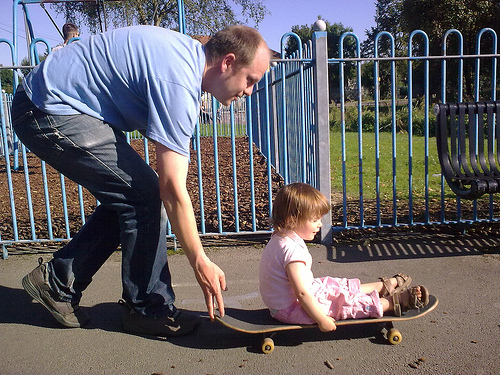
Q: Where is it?
A: This is at the walkway.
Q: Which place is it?
A: It is a walkway.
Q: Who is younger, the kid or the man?
A: The kid is younger than the man.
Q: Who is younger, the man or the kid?
A: The kid is younger than the man.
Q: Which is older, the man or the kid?
A: The man is older than the kid.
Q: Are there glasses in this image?
A: No, there are no glasses.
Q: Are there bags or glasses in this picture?
A: No, there are no glasses or bags.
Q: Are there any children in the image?
A: Yes, there is a child.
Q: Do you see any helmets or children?
A: Yes, there is a child.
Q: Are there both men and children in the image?
A: Yes, there are both a child and a man.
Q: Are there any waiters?
A: No, there are no waiters.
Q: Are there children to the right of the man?
A: Yes, there is a child to the right of the man.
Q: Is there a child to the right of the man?
A: Yes, there is a child to the right of the man.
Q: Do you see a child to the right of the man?
A: Yes, there is a child to the right of the man.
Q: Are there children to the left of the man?
A: No, the child is to the right of the man.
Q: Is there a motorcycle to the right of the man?
A: No, there is a child to the right of the man.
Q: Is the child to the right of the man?
A: Yes, the child is to the right of the man.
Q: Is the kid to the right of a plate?
A: No, the kid is to the right of the man.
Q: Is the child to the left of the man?
A: No, the child is to the right of the man.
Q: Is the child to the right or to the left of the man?
A: The child is to the right of the man.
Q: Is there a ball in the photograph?
A: No, there are no balls.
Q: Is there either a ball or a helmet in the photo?
A: No, there are no balls or helmets.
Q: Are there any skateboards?
A: Yes, there is a skateboard.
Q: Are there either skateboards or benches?
A: Yes, there is a skateboard.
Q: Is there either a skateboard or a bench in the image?
A: Yes, there is a skateboard.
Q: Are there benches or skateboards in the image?
A: Yes, there is a skateboard.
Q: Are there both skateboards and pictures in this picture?
A: No, there is a skateboard but no pictures.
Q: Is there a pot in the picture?
A: No, there are no pots.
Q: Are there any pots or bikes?
A: No, there are no pots or bikes.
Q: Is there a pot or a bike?
A: No, there are no pots or bikes.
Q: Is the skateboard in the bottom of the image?
A: Yes, the skateboard is in the bottom of the image.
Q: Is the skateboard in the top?
A: No, the skateboard is in the bottom of the image.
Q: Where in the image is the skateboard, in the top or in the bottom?
A: The skateboard is in the bottom of the image.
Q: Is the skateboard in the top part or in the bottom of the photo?
A: The skateboard is in the bottom of the image.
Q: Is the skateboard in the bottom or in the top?
A: The skateboard is in the bottom of the image.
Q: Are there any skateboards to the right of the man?
A: Yes, there is a skateboard to the right of the man.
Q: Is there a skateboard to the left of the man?
A: No, the skateboard is to the right of the man.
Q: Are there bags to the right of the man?
A: No, there is a skateboard to the right of the man.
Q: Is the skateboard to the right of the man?
A: Yes, the skateboard is to the right of the man.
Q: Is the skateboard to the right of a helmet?
A: No, the skateboard is to the right of the man.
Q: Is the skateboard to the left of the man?
A: No, the skateboard is to the right of the man.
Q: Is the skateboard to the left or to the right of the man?
A: The skateboard is to the right of the man.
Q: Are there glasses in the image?
A: No, there are no glasses.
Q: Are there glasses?
A: No, there are no glasses.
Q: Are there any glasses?
A: No, there are no glasses.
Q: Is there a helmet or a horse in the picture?
A: No, there are no helmets or horses.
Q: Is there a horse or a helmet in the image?
A: No, there are no helmets or horses.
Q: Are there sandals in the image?
A: Yes, there are sandals.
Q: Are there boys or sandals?
A: Yes, there are sandals.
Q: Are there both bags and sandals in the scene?
A: No, there are sandals but no bags.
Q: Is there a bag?
A: No, there are no bags.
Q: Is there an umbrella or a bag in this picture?
A: No, there are no bags or umbrellas.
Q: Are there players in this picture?
A: No, there are no players.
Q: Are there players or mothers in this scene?
A: No, there are no players or mothers.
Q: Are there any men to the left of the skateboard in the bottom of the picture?
A: Yes, there is a man to the left of the skateboard.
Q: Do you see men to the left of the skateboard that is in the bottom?
A: Yes, there is a man to the left of the skateboard.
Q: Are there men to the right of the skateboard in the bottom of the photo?
A: No, the man is to the left of the skateboard.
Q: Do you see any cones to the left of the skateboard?
A: No, there is a man to the left of the skateboard.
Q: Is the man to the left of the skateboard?
A: Yes, the man is to the left of the skateboard.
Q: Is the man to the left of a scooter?
A: No, the man is to the left of the skateboard.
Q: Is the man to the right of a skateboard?
A: No, the man is to the left of a skateboard.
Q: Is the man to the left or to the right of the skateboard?
A: The man is to the left of the skateboard.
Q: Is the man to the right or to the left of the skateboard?
A: The man is to the left of the skateboard.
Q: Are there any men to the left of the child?
A: Yes, there is a man to the left of the child.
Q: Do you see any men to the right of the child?
A: No, the man is to the left of the child.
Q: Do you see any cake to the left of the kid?
A: No, there is a man to the left of the kid.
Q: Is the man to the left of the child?
A: Yes, the man is to the left of the child.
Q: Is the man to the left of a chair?
A: No, the man is to the left of the child.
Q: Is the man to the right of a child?
A: No, the man is to the left of a child.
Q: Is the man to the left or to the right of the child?
A: The man is to the left of the child.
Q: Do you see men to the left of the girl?
A: Yes, there is a man to the left of the girl.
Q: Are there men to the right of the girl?
A: No, the man is to the left of the girl.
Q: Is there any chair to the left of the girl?
A: No, there is a man to the left of the girl.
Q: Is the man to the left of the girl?
A: Yes, the man is to the left of the girl.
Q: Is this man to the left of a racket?
A: No, the man is to the left of the girl.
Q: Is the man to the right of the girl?
A: No, the man is to the left of the girl.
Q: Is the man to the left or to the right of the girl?
A: The man is to the left of the girl.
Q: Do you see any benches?
A: Yes, there is a bench.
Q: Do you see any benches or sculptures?
A: Yes, there is a bench.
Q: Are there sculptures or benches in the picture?
A: Yes, there is a bench.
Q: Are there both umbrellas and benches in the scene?
A: No, there is a bench but no umbrellas.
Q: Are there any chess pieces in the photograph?
A: No, there are no chess pieces.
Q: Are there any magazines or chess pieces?
A: No, there are no chess pieces or magazines.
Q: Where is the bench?
A: The bench is on the sidewalk.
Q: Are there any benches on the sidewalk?
A: Yes, there is a bench on the sidewalk.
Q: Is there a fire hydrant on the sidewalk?
A: No, there is a bench on the sidewalk.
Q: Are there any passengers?
A: No, there are no passengers.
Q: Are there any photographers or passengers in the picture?
A: No, there are no passengers or photographers.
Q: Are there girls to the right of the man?
A: Yes, there is a girl to the right of the man.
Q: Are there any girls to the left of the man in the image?
A: No, the girl is to the right of the man.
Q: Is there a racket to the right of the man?
A: No, there is a girl to the right of the man.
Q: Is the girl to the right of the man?
A: Yes, the girl is to the right of the man.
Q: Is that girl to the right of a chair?
A: No, the girl is to the right of the man.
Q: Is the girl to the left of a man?
A: No, the girl is to the right of a man.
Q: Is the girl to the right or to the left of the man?
A: The girl is to the right of the man.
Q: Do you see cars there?
A: No, there are no cars.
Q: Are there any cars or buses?
A: No, there are no cars or buses.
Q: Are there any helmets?
A: No, there are no helmets.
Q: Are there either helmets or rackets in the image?
A: No, there are no helmets or rackets.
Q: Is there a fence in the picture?
A: Yes, there is a fence.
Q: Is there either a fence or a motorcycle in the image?
A: Yes, there is a fence.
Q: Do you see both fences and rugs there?
A: No, there is a fence but no rugs.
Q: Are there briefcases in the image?
A: No, there are no briefcases.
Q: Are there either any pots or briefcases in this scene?
A: No, there are no briefcases or pots.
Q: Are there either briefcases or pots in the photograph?
A: No, there are no briefcases or pots.